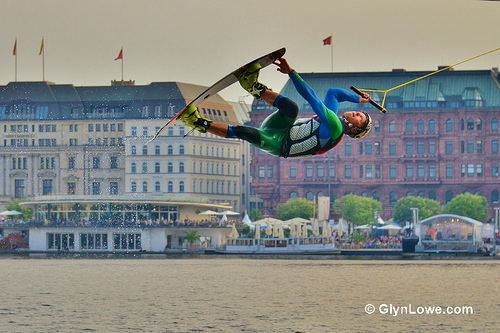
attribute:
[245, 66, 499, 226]
building — large, red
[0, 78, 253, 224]
building — large, cream colored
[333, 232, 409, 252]
people — standing, grouped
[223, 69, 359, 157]
wetsuit — multi colored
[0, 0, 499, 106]
sky — dark grey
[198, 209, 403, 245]
patio umbrellas — large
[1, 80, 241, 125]
roof — dark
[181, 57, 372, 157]
man — mid air, water skiing